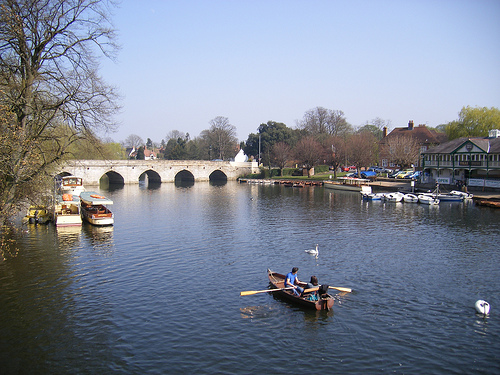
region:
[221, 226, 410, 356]
a small brown boat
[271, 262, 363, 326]
two people in a boat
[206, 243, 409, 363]
a small row boat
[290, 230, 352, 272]
a bird in the water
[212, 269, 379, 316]
two paddles to the boat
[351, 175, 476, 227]
several white boats together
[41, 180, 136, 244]
two brown and white boats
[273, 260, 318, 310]
a guy in blue shirt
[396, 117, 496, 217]
a white building with green trim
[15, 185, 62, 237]
a yellow boat by brown and white boat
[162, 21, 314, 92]
sky above the land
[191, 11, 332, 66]
sky with no clouds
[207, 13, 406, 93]
blue sky in the photo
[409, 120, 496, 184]
building next to the water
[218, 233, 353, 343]
boat in the water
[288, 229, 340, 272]
bird in the water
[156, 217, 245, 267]
water near the boat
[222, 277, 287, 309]
paddle next to boat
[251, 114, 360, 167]
trees in the distance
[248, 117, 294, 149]
leaves on a tree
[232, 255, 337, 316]
boat on the water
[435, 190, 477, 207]
boat on the water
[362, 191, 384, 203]
boat on the water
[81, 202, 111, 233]
boat on the water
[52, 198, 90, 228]
boat on the water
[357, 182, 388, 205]
boat on the water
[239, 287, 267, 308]
paddle on the boat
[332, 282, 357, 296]
paddle on the boat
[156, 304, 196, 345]
the body of water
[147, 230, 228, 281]
he water is calm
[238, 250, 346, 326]
boat on a river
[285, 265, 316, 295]
people in the boat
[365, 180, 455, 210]
boats on the river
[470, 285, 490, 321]
buoy on the water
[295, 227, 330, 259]
bird on the water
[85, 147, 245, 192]
bridge over the river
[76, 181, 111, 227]
boat on the river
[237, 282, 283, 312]
oar on the boat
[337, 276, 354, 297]
oar on the boat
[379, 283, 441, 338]
ripples in the water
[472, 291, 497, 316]
A swan that is on the lake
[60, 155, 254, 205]
A bridge that is on the lake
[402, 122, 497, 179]
A house that is on the lake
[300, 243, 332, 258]
A swan that is on the lake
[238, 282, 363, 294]
The paddles of the boat on the lake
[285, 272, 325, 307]
The people in the boat on the lake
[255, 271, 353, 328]
A boat that is on the lake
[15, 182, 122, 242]
Boats that nobody is using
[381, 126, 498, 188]
Houses next to the lake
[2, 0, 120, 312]
A tree that is in the foreground